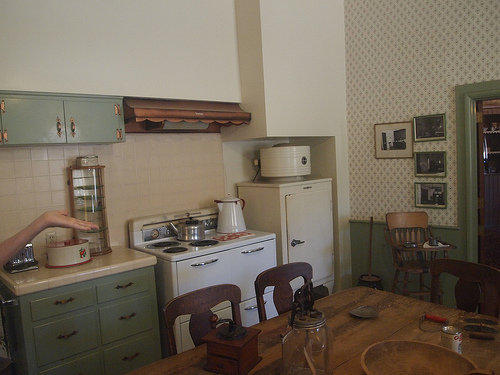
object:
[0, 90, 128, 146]
cabinets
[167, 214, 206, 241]
teapot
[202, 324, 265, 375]
grinder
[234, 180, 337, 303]
ice box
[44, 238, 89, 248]
cover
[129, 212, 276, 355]
stove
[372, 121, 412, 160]
painting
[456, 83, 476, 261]
door frame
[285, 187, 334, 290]
door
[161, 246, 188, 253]
burners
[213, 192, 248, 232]
kettle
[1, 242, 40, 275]
toaster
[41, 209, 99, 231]
hand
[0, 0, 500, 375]
kitchen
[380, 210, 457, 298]
highchair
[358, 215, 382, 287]
broom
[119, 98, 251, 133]
fan hood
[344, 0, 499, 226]
wall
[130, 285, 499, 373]
table